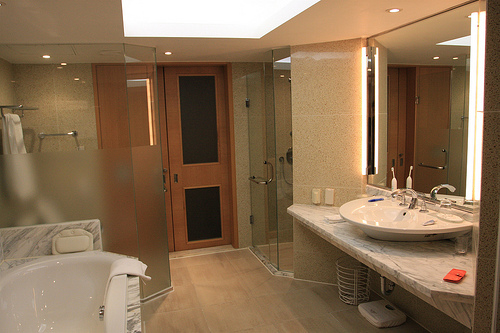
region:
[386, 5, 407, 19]
recessed lighting in the bathroom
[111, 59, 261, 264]
double sliding door in the bathroom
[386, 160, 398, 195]
one toothbrush in the toothbrush holder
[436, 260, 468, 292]
orange credit card case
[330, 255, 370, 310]
circular waste basket under counter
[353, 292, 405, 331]
white scale under counter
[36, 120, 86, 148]
silver towel bar on wall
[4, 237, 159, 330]
large white jacuzzi tub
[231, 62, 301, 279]
walk in shower with sliding doors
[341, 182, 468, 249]
modern style white bathroom sink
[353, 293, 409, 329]
WHITE SCALE ON THE FLOOR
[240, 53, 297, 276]
CLOSED GLASS SHOWER DOOR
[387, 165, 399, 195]
ELECTRIC TOOTHBRUSH ON THE SINK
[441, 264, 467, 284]
ORANGE PURSE ON THE COUNTER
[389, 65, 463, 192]
REFLECTION OF THE SHOWER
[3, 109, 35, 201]
WHITE TOWELS HANGING DOWN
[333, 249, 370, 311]
WASTE BASKET UNDER THE COUNTER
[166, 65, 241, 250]
WOODEN DOOR WITH 2 WINDOWS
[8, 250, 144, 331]
EMPTY WHITE BATHTUB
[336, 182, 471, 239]
LARGE WHITE SINK WITH CHROME FAUCET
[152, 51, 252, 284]
a brown wooden door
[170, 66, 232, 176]
window inside of a door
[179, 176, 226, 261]
window inside of a door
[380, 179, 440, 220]
silver faucet above a sink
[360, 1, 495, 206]
a mirror above a sink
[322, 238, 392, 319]
wastebasket made of metal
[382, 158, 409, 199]
white electric tooth brush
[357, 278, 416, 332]
bathroom scale under the sink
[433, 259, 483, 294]
a red wallet on the counter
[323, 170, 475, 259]
an above counter sink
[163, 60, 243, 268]
two tone wooden door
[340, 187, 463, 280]
large bathroom sink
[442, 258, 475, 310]
orange wallet laying on counter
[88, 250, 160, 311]
white towel over edge of tub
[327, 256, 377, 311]
white wire basket in bathroom floor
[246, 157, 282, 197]
silver metal handle to shower door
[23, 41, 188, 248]
glass wall in bathroom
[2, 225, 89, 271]
marbled tile around edge of tub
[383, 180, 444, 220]
silver faucet in bathroom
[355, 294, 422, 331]
white scales in bathroom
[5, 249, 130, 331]
The white bath tub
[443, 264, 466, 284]
The orange case on the counter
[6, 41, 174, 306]
The enclosed shower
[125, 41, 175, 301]
The glass shower door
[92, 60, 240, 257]
The two wood doors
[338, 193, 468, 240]
The basin of the sink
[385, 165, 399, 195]
The electronic toothbrush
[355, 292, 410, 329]
The scale under the sink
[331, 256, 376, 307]
The wastebasket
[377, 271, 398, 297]
The pipes under the sink